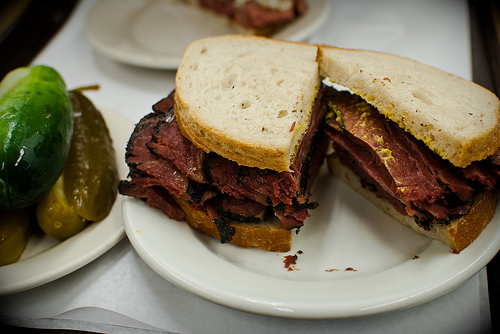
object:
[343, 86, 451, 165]
mustard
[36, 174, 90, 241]
pickle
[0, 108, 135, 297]
plate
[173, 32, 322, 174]
bread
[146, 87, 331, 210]
meat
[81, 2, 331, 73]
plate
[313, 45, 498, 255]
sandwich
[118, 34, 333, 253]
sandwich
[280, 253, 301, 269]
sauce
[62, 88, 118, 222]
pickle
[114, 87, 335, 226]
meat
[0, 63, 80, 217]
pickle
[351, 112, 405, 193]
mustard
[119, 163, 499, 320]
plate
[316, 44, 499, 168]
bread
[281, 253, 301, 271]
meat crumb